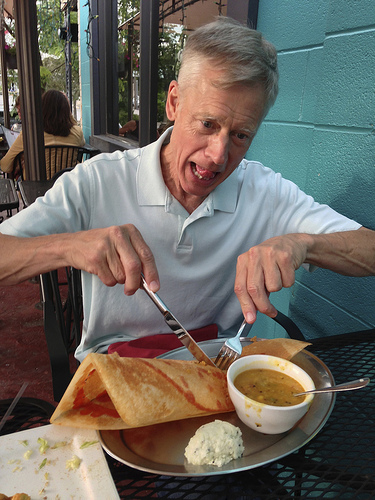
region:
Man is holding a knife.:
[137, 268, 217, 373]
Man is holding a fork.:
[212, 309, 262, 361]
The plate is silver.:
[109, 429, 286, 477]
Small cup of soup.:
[224, 354, 325, 438]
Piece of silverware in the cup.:
[288, 378, 374, 411]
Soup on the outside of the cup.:
[238, 401, 273, 429]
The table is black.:
[321, 342, 374, 497]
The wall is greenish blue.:
[277, 11, 373, 196]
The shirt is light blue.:
[90, 170, 268, 354]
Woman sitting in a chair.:
[9, 98, 89, 179]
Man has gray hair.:
[207, 44, 290, 106]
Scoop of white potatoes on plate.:
[195, 411, 255, 484]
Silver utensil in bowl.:
[307, 359, 371, 442]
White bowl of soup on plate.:
[231, 358, 305, 441]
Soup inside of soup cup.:
[248, 366, 279, 402]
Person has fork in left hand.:
[225, 291, 278, 361]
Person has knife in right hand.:
[175, 334, 219, 365]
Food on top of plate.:
[165, 350, 299, 495]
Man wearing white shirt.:
[156, 208, 213, 287]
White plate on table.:
[12, 425, 82, 495]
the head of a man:
[158, 16, 283, 198]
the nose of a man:
[201, 125, 231, 170]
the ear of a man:
[157, 75, 183, 128]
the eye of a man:
[195, 111, 222, 135]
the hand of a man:
[230, 231, 310, 325]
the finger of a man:
[230, 252, 263, 325]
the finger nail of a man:
[243, 306, 256, 323]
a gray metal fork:
[207, 305, 259, 372]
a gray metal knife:
[136, 272, 219, 370]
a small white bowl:
[223, 344, 318, 434]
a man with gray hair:
[85, 11, 372, 319]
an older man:
[72, 8, 365, 311]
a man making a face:
[82, 24, 248, 206]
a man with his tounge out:
[147, 68, 323, 224]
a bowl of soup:
[217, 346, 363, 448]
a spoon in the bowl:
[201, 351, 374, 449]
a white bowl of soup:
[212, 324, 370, 449]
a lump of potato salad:
[159, 422, 302, 490]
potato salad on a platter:
[176, 411, 259, 479]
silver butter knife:
[142, 278, 211, 366]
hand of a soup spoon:
[283, 373, 374, 400]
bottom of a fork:
[211, 319, 246, 375]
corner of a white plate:
[5, 426, 122, 495]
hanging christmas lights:
[79, 3, 117, 68]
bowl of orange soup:
[224, 355, 318, 433]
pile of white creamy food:
[186, 414, 254, 472]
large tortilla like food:
[46, 324, 314, 430]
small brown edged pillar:
[9, 1, 45, 193]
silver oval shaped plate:
[76, 307, 371, 477]